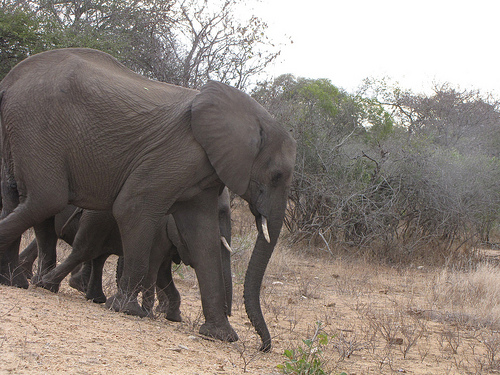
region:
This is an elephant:
[2, 45, 294, 358]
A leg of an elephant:
[100, 165, 160, 315]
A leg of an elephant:
[170, 200, 240, 345]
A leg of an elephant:
[40, 200, 100, 295]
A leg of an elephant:
[81, 251, 106, 301]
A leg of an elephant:
[0, 151, 66, 247]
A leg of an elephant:
[0, 180, 26, 290]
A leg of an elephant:
[140, 240, 160, 313]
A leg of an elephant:
[158, 261, 180, 322]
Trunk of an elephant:
[240, 169, 290, 356]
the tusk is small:
[232, 174, 297, 272]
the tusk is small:
[236, 208, 343, 326]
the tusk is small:
[232, 195, 279, 247]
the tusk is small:
[238, 215, 308, 300]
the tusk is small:
[230, 161, 325, 302]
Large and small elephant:
[15, 30, 332, 374]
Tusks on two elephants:
[187, 57, 319, 373]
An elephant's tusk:
[247, 185, 284, 260]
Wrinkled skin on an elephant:
[7, 38, 295, 357]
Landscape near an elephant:
[106, 71, 494, 374]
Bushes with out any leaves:
[283, 44, 499, 332]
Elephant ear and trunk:
[175, 43, 308, 374]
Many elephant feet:
[0, 216, 277, 345]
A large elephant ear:
[185, 57, 282, 209]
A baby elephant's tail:
[53, 177, 91, 262]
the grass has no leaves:
[307, 275, 414, 367]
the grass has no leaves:
[343, 260, 438, 364]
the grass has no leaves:
[323, 308, 430, 360]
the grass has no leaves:
[327, 335, 395, 372]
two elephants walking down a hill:
[0, 45, 301, 372]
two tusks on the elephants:
[219, 214, 271, 254]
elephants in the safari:
[2, 2, 497, 374]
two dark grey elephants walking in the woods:
[2, 45, 297, 352]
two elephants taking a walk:
[0, 0, 498, 372]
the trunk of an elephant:
[242, 245, 272, 352]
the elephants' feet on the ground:
[1, 254, 238, 341]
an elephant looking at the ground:
[0, 45, 295, 350]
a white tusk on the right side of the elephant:
[259, 217, 271, 246]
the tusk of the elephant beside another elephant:
[220, 235, 234, 256]